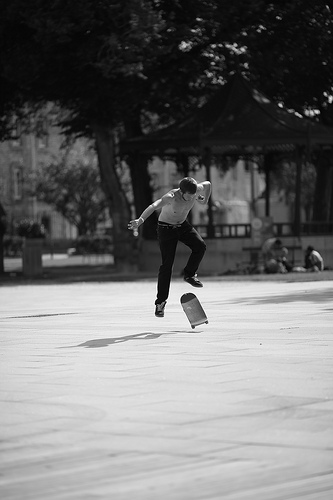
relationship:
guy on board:
[125, 176, 213, 320] [178, 288, 214, 336]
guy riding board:
[125, 176, 213, 320] [178, 288, 214, 336]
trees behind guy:
[1, 0, 322, 243] [125, 176, 213, 320]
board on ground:
[178, 288, 214, 336] [6, 267, 332, 499]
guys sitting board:
[252, 235, 321, 283] [178, 288, 214, 336]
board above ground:
[178, 288, 214, 336] [1, 283, 321, 493]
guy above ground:
[125, 176, 213, 320] [1, 283, 321, 493]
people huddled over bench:
[262, 237, 286, 271] [241, 238, 319, 265]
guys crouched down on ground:
[307, 244, 323, 271] [224, 272, 322, 284]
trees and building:
[1, 0, 322, 243] [2, 96, 290, 234]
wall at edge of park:
[134, 227, 322, 274] [1, 191, 321, 499]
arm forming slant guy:
[123, 191, 172, 237] [125, 176, 213, 320]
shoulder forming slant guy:
[156, 179, 203, 203] [125, 176, 213, 320]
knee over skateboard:
[156, 232, 208, 269] [176, 286, 209, 336]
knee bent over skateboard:
[156, 232, 208, 269] [176, 286, 209, 336]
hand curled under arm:
[194, 192, 207, 209] [192, 175, 216, 206]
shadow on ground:
[50, 323, 195, 354] [1, 283, 321, 493]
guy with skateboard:
[120, 164, 218, 325] [175, 287, 214, 331]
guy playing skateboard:
[125, 176, 213, 320] [169, 286, 216, 337]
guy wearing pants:
[125, 176, 213, 320] [151, 213, 210, 303]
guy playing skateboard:
[125, 176, 213, 320] [176, 286, 210, 331]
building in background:
[8, 58, 299, 304] [4, 23, 321, 245]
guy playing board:
[125, 176, 213, 320] [179, 293, 208, 331]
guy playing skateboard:
[125, 176, 213, 320] [167, 277, 245, 350]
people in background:
[239, 206, 322, 290] [9, 18, 323, 294]